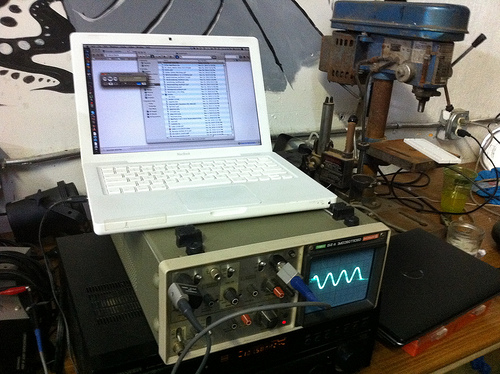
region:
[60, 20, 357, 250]
A white MacBook.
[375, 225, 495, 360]
A black laptop that is not in use.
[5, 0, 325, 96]
An image has been painted on the wall.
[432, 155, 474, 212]
A yellow plastic cup.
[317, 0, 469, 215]
A large industrial tool.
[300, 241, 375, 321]
A small screen.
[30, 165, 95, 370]
A black cord is plugged into the side of the computer.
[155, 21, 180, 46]
The MacBook has a webcam.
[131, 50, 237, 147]
iTunes is on the computer screen.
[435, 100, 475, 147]
An electrical outlet.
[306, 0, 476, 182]
A rusty drill press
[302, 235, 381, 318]
Wavy lines on the oscilloscope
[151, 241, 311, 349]
A lot of ports and controls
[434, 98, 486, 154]
An electrical outlet and cords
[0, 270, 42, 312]
A red alligator clip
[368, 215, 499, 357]
A closed black laptop computer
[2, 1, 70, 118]
Painted designs are on the wall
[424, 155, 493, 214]
A container of yellow liquid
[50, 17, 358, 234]
A white laptop computer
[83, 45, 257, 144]
A program displayed on the screen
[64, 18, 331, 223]
white laptop open in photograph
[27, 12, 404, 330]
white laptop on top of metal contraptions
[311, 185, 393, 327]
green squiggly line on screen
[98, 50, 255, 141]
browser open on laptop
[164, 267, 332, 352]
two electrical cords plugged into box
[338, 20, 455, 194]
rusted blue metal tool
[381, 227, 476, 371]
black laptop on desk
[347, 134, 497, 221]
several wires on desk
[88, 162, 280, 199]
white keyboard in photo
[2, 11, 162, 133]
white wall with black design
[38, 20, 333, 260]
A laptop computer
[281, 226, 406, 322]
an osiliscope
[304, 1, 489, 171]
A blue industrial machine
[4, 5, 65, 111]
A wavy design painted on a wall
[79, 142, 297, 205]
The keyboard of a laptop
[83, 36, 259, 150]
The screen of a laptop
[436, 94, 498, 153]
A workshop type electrical plug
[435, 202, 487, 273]
A glass of water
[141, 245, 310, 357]
A machine with a lot of plugs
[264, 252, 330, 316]
A plugged in plug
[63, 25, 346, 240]
a laptop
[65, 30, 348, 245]
a white laptop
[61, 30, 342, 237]
a laptop computer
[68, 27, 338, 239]
the laptop computer is white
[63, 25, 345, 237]
the laptop computer is turned on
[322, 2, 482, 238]
a drilling machine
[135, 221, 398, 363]
a box with wires plugged in and a computer screen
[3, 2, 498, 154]
a painting is on the wall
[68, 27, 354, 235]
the keyboard on the laptop is white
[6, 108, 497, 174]
a metal tube runs along the wall